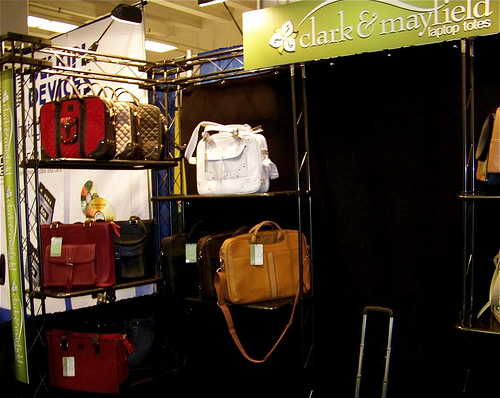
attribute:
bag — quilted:
[97, 82, 167, 162]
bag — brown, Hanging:
[210, 218, 312, 363]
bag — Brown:
[228, 211, 356, 328]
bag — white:
[216, 216, 313, 326]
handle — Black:
[358, 300, 395, 397]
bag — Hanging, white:
[183, 120, 280, 197]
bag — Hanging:
[38, 220, 120, 287]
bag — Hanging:
[41, 77, 115, 157]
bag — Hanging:
[113, 84, 163, 157]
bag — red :
[49, 335, 131, 391]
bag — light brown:
[199, 221, 329, 364]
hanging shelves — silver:
[2, 28, 498, 395]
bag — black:
[176, 190, 389, 340]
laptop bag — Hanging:
[179, 120, 276, 190]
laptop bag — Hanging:
[199, 216, 312, 309]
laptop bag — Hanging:
[40, 325, 134, 390]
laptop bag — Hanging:
[34, 214, 115, 283]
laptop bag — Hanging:
[37, 90, 109, 149]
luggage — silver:
[317, 288, 418, 395]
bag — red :
[30, 92, 112, 167]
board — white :
[51, 177, 109, 204]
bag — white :
[176, 101, 297, 212]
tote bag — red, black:
[37, 78, 114, 160]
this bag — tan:
[227, 215, 347, 287]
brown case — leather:
[213, 217, 311, 364]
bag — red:
[29, 325, 122, 393]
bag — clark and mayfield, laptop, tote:
[191, 113, 275, 185]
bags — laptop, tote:
[36, 81, 165, 161]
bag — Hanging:
[203, 116, 280, 206]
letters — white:
[296, 2, 493, 52]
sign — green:
[240, 1, 487, 97]